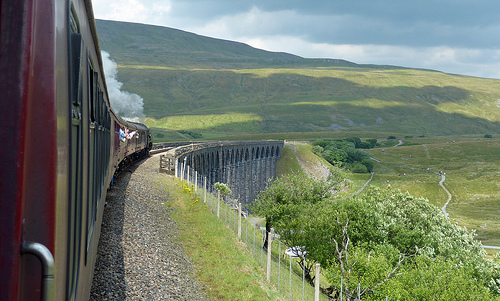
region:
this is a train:
[39, 26, 108, 236]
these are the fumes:
[106, 52, 125, 98]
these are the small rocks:
[118, 215, 155, 300]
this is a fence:
[177, 148, 229, 224]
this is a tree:
[289, 171, 341, 266]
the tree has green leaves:
[300, 225, 323, 245]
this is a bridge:
[177, 133, 266, 186]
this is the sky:
[336, 6, 473, 66]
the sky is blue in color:
[413, 2, 447, 20]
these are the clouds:
[336, 43, 403, 56]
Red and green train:
[11, 10, 166, 278]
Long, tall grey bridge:
[149, 130, 295, 217]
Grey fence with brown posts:
[169, 137, 291, 294]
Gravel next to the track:
[103, 145, 207, 285]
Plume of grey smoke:
[87, 37, 162, 139]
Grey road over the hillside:
[422, 152, 467, 234]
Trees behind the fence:
[253, 159, 494, 295]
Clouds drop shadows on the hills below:
[117, 30, 464, 160]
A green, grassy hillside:
[110, 15, 482, 198]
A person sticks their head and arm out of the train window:
[113, 122, 153, 150]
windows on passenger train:
[59, 33, 112, 141]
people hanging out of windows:
[114, 119, 146, 150]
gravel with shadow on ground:
[103, 203, 165, 280]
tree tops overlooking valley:
[380, 183, 481, 256]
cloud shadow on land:
[295, 74, 385, 103]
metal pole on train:
[16, 231, 63, 293]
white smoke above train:
[109, 83, 155, 128]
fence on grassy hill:
[199, 174, 274, 256]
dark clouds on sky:
[284, 9, 414, 54]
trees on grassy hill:
[254, 228, 327, 281]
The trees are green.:
[277, 151, 407, 265]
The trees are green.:
[231, 123, 383, 261]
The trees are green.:
[296, 179, 440, 291]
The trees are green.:
[311, 176, 382, 291]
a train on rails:
[19, 19, 161, 289]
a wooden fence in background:
[190, 169, 345, 299]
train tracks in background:
[163, 121, 319, 167]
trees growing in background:
[263, 186, 489, 299]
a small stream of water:
[408, 146, 497, 238]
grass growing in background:
[400, 153, 492, 229]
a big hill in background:
[112, 21, 377, 131]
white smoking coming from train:
[90, 32, 170, 135]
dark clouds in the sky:
[248, 7, 459, 64]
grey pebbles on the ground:
[118, 215, 158, 295]